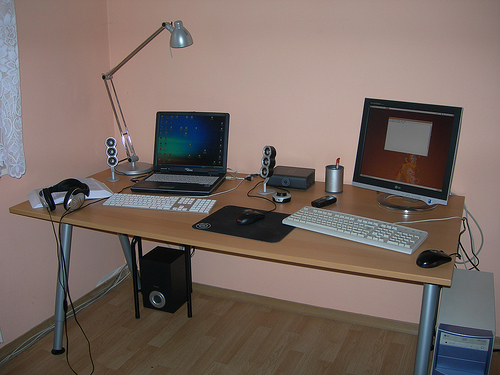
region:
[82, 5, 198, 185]
a lamp over a table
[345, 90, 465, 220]
a screen on a desk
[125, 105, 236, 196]
a laptop over the table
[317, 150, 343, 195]
a can with pens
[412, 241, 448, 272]
a computer mouse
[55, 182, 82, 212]
a computer mouse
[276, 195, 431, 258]
the laptop is color white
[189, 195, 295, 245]
a computer mouse color black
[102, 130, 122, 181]
a speaker of computer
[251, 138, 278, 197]
a speaker of computer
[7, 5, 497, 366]
computer equipment and desk in a corner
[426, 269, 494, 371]
tan and blue CPU of a computer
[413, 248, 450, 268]
black computer mouse on a tan desk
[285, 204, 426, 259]
white keyboard on a tan desk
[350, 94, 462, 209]
computer monitor on a tan desk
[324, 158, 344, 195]
pencil holder on a tan desk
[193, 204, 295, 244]
black mouse pad on a tan desk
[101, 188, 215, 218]
white keyboard on a tan desk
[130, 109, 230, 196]
black laptop computer on a tan desk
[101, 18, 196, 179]
hinged lamp on a tan desk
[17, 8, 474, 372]
desk set up at home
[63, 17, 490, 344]
desk with two computers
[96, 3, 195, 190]
tall silver desk lamp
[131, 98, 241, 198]
black laptop open on desk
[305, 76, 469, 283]
desktop computer on wooden desk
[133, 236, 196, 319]
black bass speaker underneath desk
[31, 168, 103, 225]
large black headphones on desk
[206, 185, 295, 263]
black mouse pad with black mouse on desk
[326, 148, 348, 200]
pencil can with single pen inside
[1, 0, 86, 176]
lace curtain and pink painted wall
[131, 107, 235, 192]
The black laptop on the table.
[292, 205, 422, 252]
The keyboard in front of the computer monitor.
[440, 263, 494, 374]
The computer tower on the floor.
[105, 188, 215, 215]
The keyboard in front of the laptop.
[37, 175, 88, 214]
The earphones on the table.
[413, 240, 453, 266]
The mouse on the right side of the table.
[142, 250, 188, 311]
The speaker under the table.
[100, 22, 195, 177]
The lamp on the table.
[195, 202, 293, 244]
The large mouse pad in the middle of the table.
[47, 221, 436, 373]
The legs of the table.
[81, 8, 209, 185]
Silver lamp on desk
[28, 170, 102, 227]
Head phones on the desk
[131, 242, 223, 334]
Speaker on the floor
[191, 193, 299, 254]
Mouspad on the desk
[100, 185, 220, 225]
keyboard on the desk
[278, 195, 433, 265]
keyboard on the desk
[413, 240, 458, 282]
Mouse on the desk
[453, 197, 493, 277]
Wires hanging from desk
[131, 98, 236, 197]
Laptop on the desk